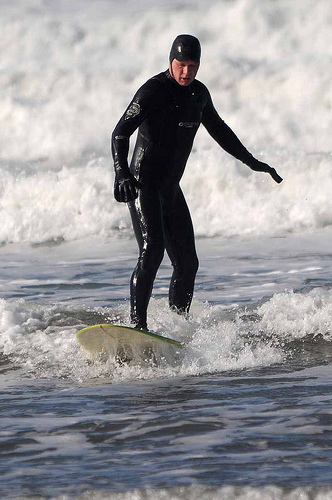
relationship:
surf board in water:
[73, 324, 199, 372] [2, 350, 330, 496]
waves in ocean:
[3, 299, 331, 378] [5, 7, 327, 495]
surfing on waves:
[71, 32, 287, 376] [3, 299, 331, 378]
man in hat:
[110, 32, 284, 328] [168, 32, 206, 69]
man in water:
[110, 32, 284, 328] [2, 350, 330, 496]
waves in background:
[8, 23, 332, 238] [3, 10, 332, 131]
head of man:
[167, 32, 203, 91] [110, 32, 284, 328]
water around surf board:
[2, 350, 330, 496] [73, 322, 199, 372]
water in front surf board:
[2, 350, 330, 496] [73, 322, 199, 372]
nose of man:
[181, 67, 191, 78] [110, 32, 284, 328]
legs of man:
[126, 176, 204, 339] [110, 32, 284, 328]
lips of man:
[180, 74, 193, 86] [110, 32, 284, 328]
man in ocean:
[110, 32, 284, 328] [5, 7, 327, 495]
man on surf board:
[110, 32, 284, 328] [73, 324, 199, 372]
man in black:
[110, 32, 284, 328] [160, 100, 179, 180]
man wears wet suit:
[110, 32, 284, 328] [110, 88, 284, 331]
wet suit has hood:
[110, 88, 284, 331] [168, 32, 206, 69]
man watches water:
[110, 32, 284, 328] [2, 350, 330, 496]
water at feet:
[2, 350, 330, 496] [115, 319, 212, 339]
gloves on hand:
[239, 154, 288, 188] [244, 160, 299, 190]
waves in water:
[3, 299, 331, 378] [2, 350, 330, 496]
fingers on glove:
[270, 165, 286, 188] [239, 154, 288, 188]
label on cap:
[171, 41, 192, 57] [168, 32, 206, 69]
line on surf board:
[93, 324, 121, 347] [73, 324, 199, 372]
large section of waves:
[10, 17, 330, 218] [8, 23, 332, 238]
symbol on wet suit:
[119, 96, 145, 121] [110, 88, 284, 331]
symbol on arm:
[119, 96, 145, 121] [108, 84, 162, 175]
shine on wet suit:
[127, 184, 155, 266] [110, 88, 284, 331]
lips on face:
[180, 74, 193, 86] [172, 53, 201, 87]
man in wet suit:
[110, 32, 284, 328] [110, 88, 284, 331]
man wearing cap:
[110, 32, 284, 328] [168, 32, 206, 69]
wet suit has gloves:
[110, 88, 284, 331] [239, 154, 288, 188]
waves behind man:
[8, 23, 332, 238] [110, 32, 284, 328]